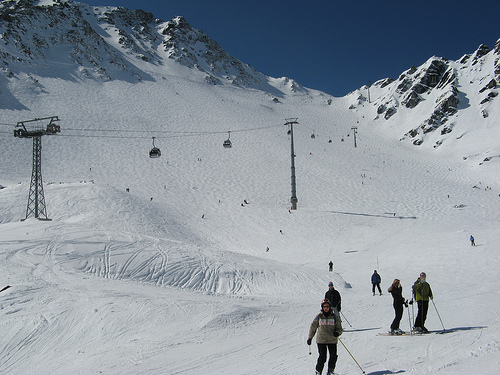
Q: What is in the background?
A: Blue sky.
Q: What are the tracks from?
A: Skiers.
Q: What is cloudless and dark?
A: Sky.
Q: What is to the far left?
A: Mountain peaks.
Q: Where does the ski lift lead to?
A: Snowy mountain.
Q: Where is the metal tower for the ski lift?
A: Left.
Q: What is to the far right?
A: Ski mountains.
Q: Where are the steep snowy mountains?
A: Far left.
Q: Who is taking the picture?
A: Another skier.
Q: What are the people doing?
A: Skiing.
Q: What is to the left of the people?
A: A tall mountain.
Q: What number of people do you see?
A: 6 people.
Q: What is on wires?
A: The ski lifts.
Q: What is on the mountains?
A: Snow.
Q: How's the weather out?
A: Clear and cold.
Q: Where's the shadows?
A: On the ground in the snow.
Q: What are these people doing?
A: Skiing.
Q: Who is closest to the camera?
A: Woman in grey jacket.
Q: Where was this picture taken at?
A: Ski resort.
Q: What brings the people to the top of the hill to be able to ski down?
A: Ski lift.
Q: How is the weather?
A: Sunny.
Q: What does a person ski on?
A: Snow.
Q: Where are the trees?
A: No trees.